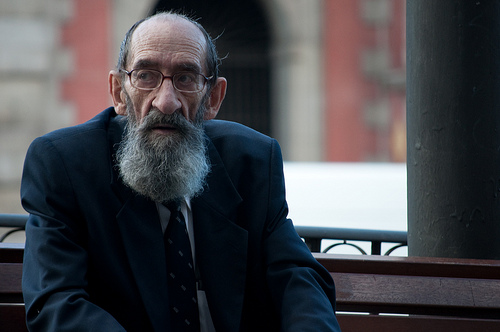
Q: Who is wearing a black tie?
A: The old man.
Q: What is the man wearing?
A: A suit.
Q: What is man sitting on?
A: On a bench.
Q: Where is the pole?
A: Behind the bench.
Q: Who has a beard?
A: The old man.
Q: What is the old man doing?
A: Sitting.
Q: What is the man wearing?
A: A suit.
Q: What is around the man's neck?
A: A tie.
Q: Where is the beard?
A: On the man.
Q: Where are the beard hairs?
A: On the man.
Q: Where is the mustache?
A: On the man.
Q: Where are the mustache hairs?
A: On the man.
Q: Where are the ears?
A: On the man.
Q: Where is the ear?
A: On the man.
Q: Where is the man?
A: On the bench.